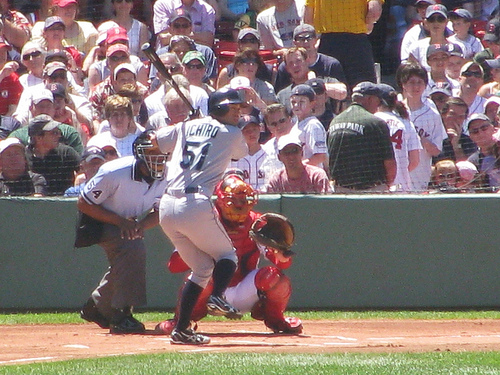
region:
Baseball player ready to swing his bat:
[136, 41, 249, 346]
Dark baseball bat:
[138, 38, 201, 118]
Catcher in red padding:
[152, 163, 309, 334]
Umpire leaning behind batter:
[72, 125, 172, 335]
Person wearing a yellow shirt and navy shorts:
[301, 1, 386, 88]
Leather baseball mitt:
[247, 210, 295, 251]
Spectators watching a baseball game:
[0, 0, 498, 205]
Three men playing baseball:
[75, 85, 304, 344]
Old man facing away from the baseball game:
[324, 79, 396, 195]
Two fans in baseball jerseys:
[370, 59, 445, 192]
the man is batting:
[117, 30, 254, 349]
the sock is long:
[210, 255, 242, 298]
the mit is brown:
[248, 203, 303, 258]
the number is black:
[172, 132, 210, 176]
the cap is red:
[100, 20, 128, 45]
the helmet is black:
[201, 83, 245, 118]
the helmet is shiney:
[205, 78, 243, 125]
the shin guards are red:
[259, 266, 301, 328]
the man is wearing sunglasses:
[465, 123, 490, 135]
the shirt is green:
[316, 107, 404, 187]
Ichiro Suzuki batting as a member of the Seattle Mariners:
[128, 33, 260, 365]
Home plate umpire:
[69, 120, 186, 343]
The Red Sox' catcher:
[153, 170, 322, 350]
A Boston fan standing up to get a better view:
[373, 63, 450, 198]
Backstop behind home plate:
[0, 196, 498, 315]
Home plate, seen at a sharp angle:
[215, 330, 278, 348]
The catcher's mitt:
[247, 206, 301, 263]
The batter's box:
[60, 330, 402, 348]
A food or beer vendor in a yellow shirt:
[295, 0, 388, 112]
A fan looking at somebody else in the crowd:
[13, 114, 83, 196]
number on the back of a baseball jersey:
[178, 136, 213, 173]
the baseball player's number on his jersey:
[175, 138, 210, 172]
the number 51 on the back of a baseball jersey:
[176, 139, 213, 170]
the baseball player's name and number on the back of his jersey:
[178, 120, 222, 170]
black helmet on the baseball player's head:
[205, 86, 246, 113]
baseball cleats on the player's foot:
[171, 325, 211, 342]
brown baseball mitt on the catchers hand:
[247, 212, 297, 252]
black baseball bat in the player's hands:
[139, 41, 206, 116]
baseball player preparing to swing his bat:
[140, 41, 254, 343]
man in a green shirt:
[325, 80, 397, 192]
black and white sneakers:
[161, 323, 233, 351]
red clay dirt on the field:
[343, 321, 437, 346]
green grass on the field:
[13, 312, 58, 324]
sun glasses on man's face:
[14, 48, 64, 70]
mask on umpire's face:
[127, 130, 189, 199]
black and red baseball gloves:
[250, 207, 312, 259]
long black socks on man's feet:
[168, 279, 218, 335]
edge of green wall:
[310, 177, 427, 203]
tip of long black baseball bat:
[136, 36, 178, 61]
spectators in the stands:
[82, 33, 395, 130]